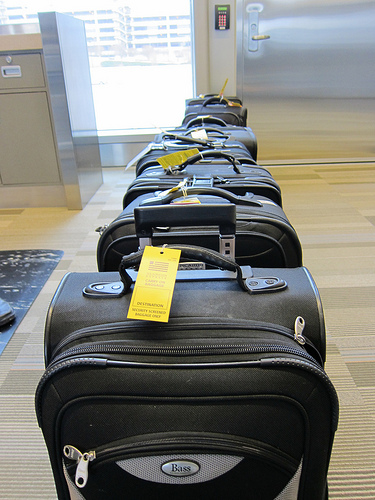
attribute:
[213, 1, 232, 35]
keypad — hanging, digital, red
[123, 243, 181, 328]
tag — yellow, attached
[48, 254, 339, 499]
suitcase — black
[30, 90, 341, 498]
suitcases — standing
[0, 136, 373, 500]
floor — beige, wooden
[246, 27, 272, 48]
handle — metal, copper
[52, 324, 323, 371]
zipper — black, metal, shut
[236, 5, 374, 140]
door — steel, metallic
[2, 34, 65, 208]
drawer — beige, shut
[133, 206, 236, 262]
handle — black, pullable, up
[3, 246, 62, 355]
rug — black